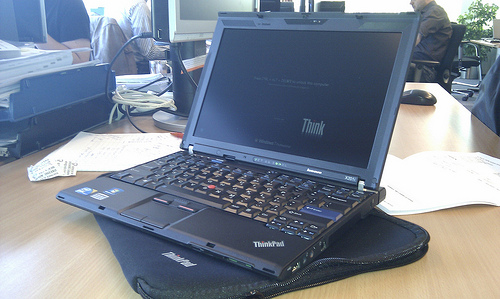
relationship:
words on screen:
[295, 114, 323, 131] [242, 49, 358, 142]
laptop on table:
[204, 51, 338, 250] [28, 231, 66, 260]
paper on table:
[66, 145, 101, 171] [28, 231, 66, 260]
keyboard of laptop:
[189, 167, 292, 225] [204, 51, 338, 250]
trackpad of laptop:
[141, 188, 180, 227] [204, 51, 338, 250]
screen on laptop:
[242, 49, 358, 142] [204, 51, 338, 250]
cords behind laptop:
[105, 105, 171, 135] [204, 51, 338, 250]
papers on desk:
[129, 118, 164, 144] [422, 240, 425, 255]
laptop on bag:
[204, 51, 338, 250] [36, 103, 98, 145]